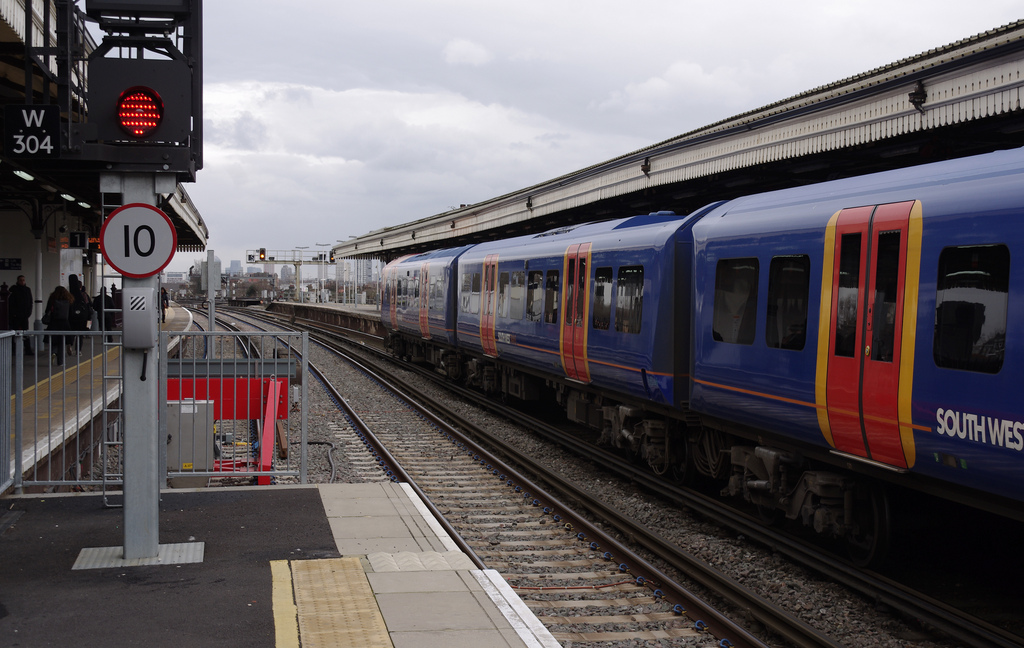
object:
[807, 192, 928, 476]
doors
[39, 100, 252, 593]
post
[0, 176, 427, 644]
platform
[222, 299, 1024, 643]
tracks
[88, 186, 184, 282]
sign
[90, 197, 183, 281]
number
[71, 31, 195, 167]
light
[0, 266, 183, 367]
people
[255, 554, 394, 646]
tile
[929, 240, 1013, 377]
window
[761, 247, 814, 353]
window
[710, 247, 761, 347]
window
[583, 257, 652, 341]
window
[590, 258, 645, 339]
window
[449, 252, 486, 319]
window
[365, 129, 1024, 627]
train